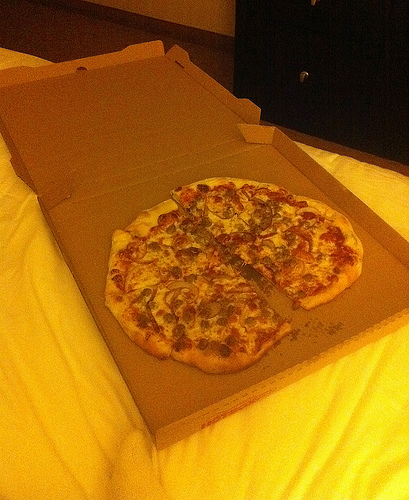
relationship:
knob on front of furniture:
[292, 65, 318, 95] [232, 0, 407, 177]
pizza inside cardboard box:
[101, 172, 363, 378] [0, 38, 409, 450]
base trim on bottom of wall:
[146, 11, 247, 40] [62, 1, 243, 48]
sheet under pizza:
[0, 48, 408, 498] [154, 194, 295, 311]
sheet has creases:
[0, 48, 408, 498] [276, 334, 403, 496]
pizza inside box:
[101, 172, 363, 378] [27, 75, 202, 145]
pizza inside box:
[101, 172, 363, 378] [0, 32, 409, 451]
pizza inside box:
[101, 172, 363, 378] [1, 35, 405, 351]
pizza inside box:
[101, 172, 363, 378] [14, 29, 253, 188]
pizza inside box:
[101, 172, 363, 378] [31, 53, 397, 446]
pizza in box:
[101, 172, 363, 378] [0, 32, 409, 451]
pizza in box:
[101, 172, 363, 378] [33, 41, 307, 162]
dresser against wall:
[234, 1, 408, 174] [93, 1, 236, 43]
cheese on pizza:
[63, 160, 368, 378] [112, 195, 259, 353]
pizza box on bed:
[21, 94, 369, 456] [14, 206, 338, 496]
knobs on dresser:
[296, 1, 314, 89] [242, 16, 398, 124]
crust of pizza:
[105, 165, 178, 221] [89, 170, 364, 363]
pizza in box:
[101, 172, 363, 378] [14, 62, 177, 195]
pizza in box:
[141, 202, 211, 252] [0, 32, 409, 451]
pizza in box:
[101, 172, 363, 378] [19, 64, 364, 359]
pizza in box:
[101, 172, 363, 378] [24, 75, 354, 422]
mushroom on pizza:
[202, 300, 223, 317] [101, 172, 363, 378]